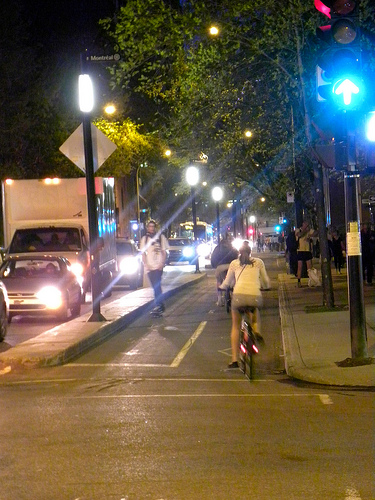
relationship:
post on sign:
[67, 76, 120, 340] [59, 120, 120, 177]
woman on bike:
[227, 241, 274, 308] [234, 322, 272, 380]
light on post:
[61, 73, 110, 114] [67, 76, 120, 340]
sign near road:
[59, 120, 120, 177] [63, 349, 337, 495]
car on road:
[6, 256, 77, 324] [63, 349, 337, 495]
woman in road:
[227, 241, 274, 308] [63, 349, 337, 495]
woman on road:
[227, 241, 274, 308] [63, 349, 337, 495]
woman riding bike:
[227, 241, 274, 308] [234, 322, 272, 380]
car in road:
[6, 256, 77, 324] [63, 349, 337, 495]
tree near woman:
[152, 23, 313, 186] [227, 241, 274, 308]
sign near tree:
[59, 120, 120, 177] [152, 23, 313, 186]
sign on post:
[59, 120, 120, 177] [67, 76, 120, 340]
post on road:
[67, 76, 120, 340] [63, 349, 337, 495]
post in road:
[67, 76, 120, 340] [63, 349, 337, 495]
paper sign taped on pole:
[331, 221, 369, 277] [328, 196, 373, 381]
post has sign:
[67, 76, 120, 340] [59, 120, 120, 177]